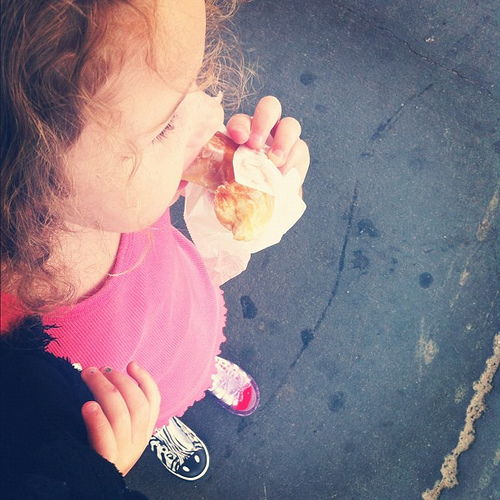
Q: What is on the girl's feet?
A: Shoes.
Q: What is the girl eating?
A: Doughnut.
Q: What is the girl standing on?
A: Asphalt.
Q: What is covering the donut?
A: Wrapper.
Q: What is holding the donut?
A: Hand.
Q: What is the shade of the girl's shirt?
A: Pink.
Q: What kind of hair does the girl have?
A: Curly.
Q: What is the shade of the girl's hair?
A: Brown.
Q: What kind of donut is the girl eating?
A: Glazed.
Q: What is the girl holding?
A: Donut.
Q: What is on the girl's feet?
A: Shoes.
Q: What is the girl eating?
A: A donut.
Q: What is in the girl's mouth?
A: Donut.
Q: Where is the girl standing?
A: On pavement.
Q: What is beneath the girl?
A: Pavement.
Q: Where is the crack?
A: In the pavement.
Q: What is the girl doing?
A: Eating.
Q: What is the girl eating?
A: Donut.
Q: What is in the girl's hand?
A: Donut.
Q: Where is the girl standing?
A: Pavement.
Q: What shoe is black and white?
A: The girl's right one.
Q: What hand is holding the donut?
A: The girl's left one.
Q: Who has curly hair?
A: The young girl.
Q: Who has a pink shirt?
A: The young girl.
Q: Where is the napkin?
A: In the girl's hand.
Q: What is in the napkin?
A: Donut.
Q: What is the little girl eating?
A: Donut.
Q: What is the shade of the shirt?
A: Pink.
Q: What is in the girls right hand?
A: Teddy.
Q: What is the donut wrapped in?
A: Napkin.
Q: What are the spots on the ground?
A: Grease spots.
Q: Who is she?
A: A girl.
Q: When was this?
A: Daytime.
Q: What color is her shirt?
A: Pink.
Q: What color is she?
A: White.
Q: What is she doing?
A: Eating.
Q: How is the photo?
A: Clear.